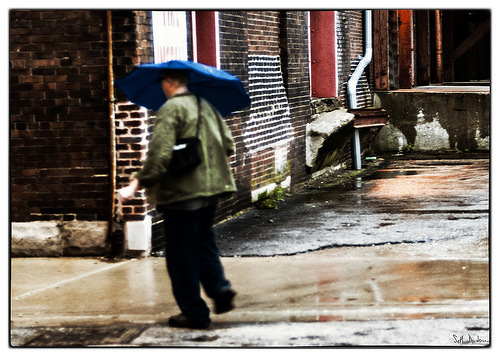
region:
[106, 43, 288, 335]
Woman walking down sidewalk with open umbrella.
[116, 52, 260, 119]
An open blue umbrella.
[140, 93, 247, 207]
Woman dressed in green jacket.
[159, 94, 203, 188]
Woman carrying black purse over shoulder.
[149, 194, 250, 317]
Woman wearing black pants.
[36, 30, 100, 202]
Red brick on side of wall.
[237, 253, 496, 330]
Rain soaked sidewalk reflecting red building.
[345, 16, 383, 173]
Downpipe on gutter mounted against building wall.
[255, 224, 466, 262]
Long crack in concrete leading into alley.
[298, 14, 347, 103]
Red indentation indicating window on building wall.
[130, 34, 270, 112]
blue umbrella above person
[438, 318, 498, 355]
name in bottom right corner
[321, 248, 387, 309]
water on the ground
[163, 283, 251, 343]
shoes of the man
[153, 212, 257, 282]
pants of the man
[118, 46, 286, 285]
man with back towards camera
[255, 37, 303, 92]
brick wall near the man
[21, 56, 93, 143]
brown brick wall next to man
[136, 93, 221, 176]
jacket on the person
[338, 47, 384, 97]
pipe on the building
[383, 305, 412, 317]
part of a floor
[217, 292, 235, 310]
sole of a shoe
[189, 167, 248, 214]
edge of a coat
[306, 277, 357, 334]
part of a floor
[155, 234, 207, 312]
part of a trouser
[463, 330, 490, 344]
part of a graphic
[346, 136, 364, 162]
par of a post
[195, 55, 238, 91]
part of an umbrella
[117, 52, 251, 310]
a man holding a blue umbrella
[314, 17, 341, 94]
a red wooden door framw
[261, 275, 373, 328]
gray wet asphalt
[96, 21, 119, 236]
a rusty pipe on the side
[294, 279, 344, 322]
a reflection on the ground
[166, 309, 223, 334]
a black shoe on the ground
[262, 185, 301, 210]
a small plant next to the building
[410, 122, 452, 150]
a white patch on a low wall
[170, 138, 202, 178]
a black bag hanging on a shoulder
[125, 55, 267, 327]
a man wearing dark blue pants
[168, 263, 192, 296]
part of a trouser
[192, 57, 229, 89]
edge of an umbrella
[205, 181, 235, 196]
edge of a coat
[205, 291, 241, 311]
edge of a shoe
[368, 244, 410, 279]
part of a floor